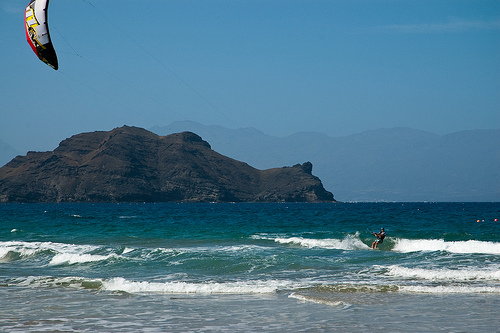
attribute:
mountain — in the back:
[1, 117, 348, 211]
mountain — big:
[4, 124, 341, 223]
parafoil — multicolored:
[23, 2, 58, 66]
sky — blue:
[0, 0, 498, 156]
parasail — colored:
[23, 0, 58, 70]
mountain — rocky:
[1, 124, 336, 202]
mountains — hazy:
[147, 120, 499, 200]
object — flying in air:
[21, 7, 82, 72]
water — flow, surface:
[0, 203, 500, 330]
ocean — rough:
[4, 197, 497, 329]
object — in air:
[19, 3, 71, 81]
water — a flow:
[87, 213, 375, 280]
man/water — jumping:
[359, 220, 397, 259]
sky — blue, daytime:
[167, 14, 446, 115]